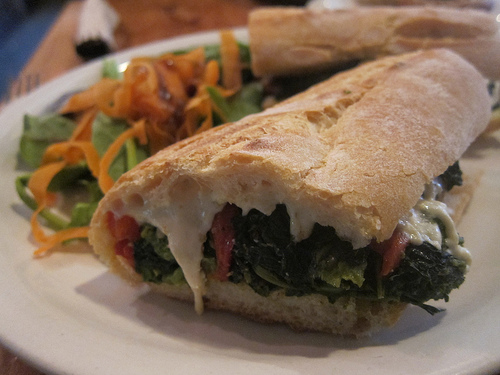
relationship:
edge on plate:
[0, 347, 117, 373] [6, 24, 496, 373]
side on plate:
[429, 147, 496, 373] [6, 24, 496, 373]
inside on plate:
[21, 253, 292, 353] [6, 24, 496, 373]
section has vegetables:
[11, 36, 250, 253] [93, 79, 165, 141]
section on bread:
[312, 103, 393, 162] [83, 46, 493, 334]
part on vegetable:
[409, 275, 427, 292] [377, 238, 470, 307]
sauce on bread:
[119, 178, 447, 307] [83, 46, 493, 334]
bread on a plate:
[83, 46, 493, 334] [44, 55, 431, 373]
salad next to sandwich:
[14, 31, 311, 289] [118, 63, 467, 371]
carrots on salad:
[116, 52, 226, 160] [44, 50, 188, 230]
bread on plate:
[83, 46, 493, 334] [39, 55, 496, 359]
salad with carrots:
[14, 31, 311, 289] [116, 52, 226, 160]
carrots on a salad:
[116, 52, 226, 160] [40, 30, 422, 289]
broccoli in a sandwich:
[226, 216, 422, 300] [140, 62, 471, 302]